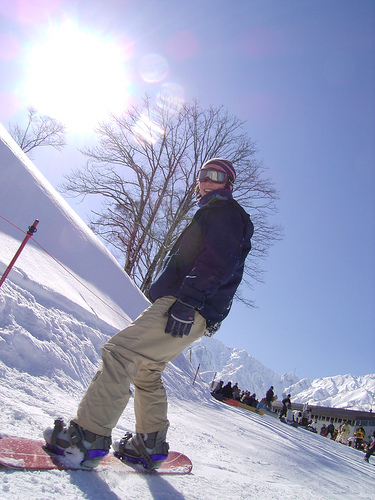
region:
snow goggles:
[198, 170, 223, 182]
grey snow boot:
[115, 427, 170, 457]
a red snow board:
[4, 435, 192, 478]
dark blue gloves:
[161, 301, 200, 336]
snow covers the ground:
[8, 410, 293, 497]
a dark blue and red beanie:
[202, 153, 233, 171]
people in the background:
[215, 376, 253, 407]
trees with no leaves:
[111, 96, 217, 263]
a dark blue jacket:
[176, 196, 241, 304]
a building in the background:
[296, 398, 374, 446]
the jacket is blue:
[155, 188, 254, 332]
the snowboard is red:
[6, 423, 203, 483]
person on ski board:
[2, 155, 258, 479]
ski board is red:
[0, 408, 200, 490]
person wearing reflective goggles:
[188, 151, 229, 190]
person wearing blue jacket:
[136, 188, 256, 323]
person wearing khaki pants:
[75, 285, 211, 450]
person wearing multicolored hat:
[189, 150, 237, 182]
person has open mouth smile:
[196, 183, 217, 195]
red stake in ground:
[0, 191, 53, 324]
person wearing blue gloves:
[156, 288, 201, 341]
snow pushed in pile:
[7, 135, 212, 427]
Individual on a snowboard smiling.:
[0, 143, 254, 493]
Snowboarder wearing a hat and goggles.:
[195, 156, 237, 214]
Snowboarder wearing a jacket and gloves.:
[153, 157, 253, 339]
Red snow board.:
[0, 435, 193, 472]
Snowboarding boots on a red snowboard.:
[1, 416, 191, 469]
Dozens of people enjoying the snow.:
[210, 371, 373, 458]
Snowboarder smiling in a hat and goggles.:
[145, 157, 253, 338]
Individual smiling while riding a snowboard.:
[1, 157, 253, 477]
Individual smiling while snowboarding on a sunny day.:
[1, 160, 246, 470]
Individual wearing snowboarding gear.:
[0, 156, 252, 471]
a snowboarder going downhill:
[1, 159, 254, 475]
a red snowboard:
[0, 436, 192, 475]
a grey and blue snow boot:
[42, 421, 111, 471]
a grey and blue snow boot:
[113, 431, 168, 471]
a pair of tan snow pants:
[74, 296, 207, 436]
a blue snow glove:
[162, 302, 194, 338]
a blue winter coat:
[149, 190, 252, 330]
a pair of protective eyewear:
[195, 167, 226, 183]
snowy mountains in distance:
[189, 336, 373, 412]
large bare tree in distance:
[55, 88, 285, 316]